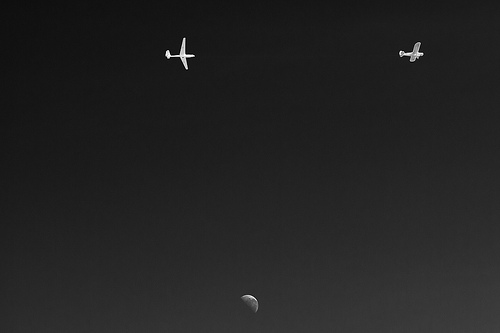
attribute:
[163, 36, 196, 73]
plane — white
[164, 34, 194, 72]
plane — small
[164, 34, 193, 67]
plane — white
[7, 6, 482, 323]
sky — black, white, dark, night, nighttime 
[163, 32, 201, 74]
plane — white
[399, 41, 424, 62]
plane — white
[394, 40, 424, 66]
plane — white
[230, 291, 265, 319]
moon — grey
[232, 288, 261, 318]
moon — half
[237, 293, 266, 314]
moon — dark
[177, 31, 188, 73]
wings — long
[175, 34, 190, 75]
wings — long, white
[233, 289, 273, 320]
moon — mostly grey, half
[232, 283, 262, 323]
moon — grey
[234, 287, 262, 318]
moon — grey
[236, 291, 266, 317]
moon — half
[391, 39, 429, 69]
plane — white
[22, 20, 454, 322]
sky — dark, black, night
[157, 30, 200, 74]
plane — larger, white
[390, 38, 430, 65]
plane — white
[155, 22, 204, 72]
plane — image, black, white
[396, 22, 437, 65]
plane — image, black, white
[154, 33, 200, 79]
plane — surreal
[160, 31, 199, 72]
plane — bigger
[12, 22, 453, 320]
photo — outer space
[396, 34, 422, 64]
plane — white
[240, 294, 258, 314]
moon — half, partially obscured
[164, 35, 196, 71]
glider — white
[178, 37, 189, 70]
wingspan — large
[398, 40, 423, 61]
plane — white, prop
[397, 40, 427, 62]
plane — prop, white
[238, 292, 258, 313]
moon — half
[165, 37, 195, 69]
airplane — rotorless, flying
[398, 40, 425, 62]
plane — white, making turn, small, flying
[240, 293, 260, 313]
moon — light sided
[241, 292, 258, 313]
lunar eclipse — partial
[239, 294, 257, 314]
moon — dark sided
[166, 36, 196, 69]
plane — large, white, flying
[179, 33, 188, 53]
wing — long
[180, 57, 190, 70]
wing — long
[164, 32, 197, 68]
airplane — white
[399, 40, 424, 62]
airplane — white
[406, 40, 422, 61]
wings — rounded 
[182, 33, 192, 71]
wings — pointed